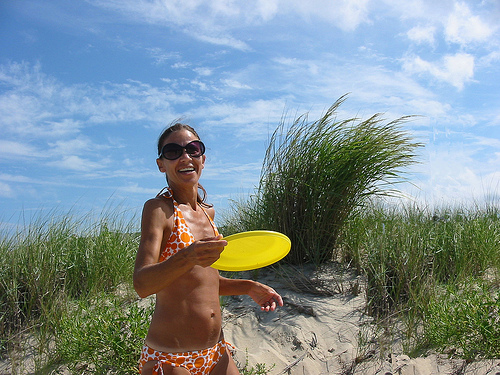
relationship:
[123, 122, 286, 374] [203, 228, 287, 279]
woman holding frisbee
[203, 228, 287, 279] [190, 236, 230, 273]
frisbee in hand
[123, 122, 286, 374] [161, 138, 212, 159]
woman wearing sunglasses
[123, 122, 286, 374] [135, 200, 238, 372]
woman wearing swimsuit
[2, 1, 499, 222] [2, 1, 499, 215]
sky with clouds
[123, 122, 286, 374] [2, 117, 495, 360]
woman standing in front of grass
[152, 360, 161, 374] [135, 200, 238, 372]
tie of a swimsuit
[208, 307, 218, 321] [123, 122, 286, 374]
belly button of woman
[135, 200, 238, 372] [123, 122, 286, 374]
swimsuit on a woman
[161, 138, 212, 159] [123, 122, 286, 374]
sunglasses on a woman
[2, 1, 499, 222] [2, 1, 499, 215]
sky fille with clouds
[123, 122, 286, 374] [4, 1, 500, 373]
woman at beach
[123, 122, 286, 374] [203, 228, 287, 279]
woman throwing frisbee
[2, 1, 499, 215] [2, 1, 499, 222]
clouds in sky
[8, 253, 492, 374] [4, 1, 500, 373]
sand at beach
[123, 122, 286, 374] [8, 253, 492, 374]
woman playing in sand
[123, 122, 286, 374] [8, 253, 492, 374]
woman having fun in sand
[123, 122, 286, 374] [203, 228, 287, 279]
woman playing with frisbee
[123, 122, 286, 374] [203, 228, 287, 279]
woman going to throw a frisbee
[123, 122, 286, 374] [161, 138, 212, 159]
woman has sunglasses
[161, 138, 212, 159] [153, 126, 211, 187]
sunglasses on her head